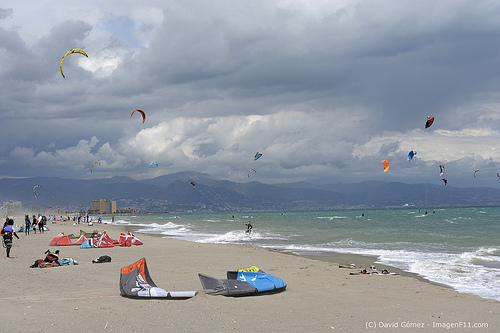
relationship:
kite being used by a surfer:
[379, 160, 390, 174] [244, 218, 253, 235]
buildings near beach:
[0, 195, 135, 215] [2, 219, 499, 331]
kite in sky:
[379, 160, 390, 174] [11, 17, 481, 197]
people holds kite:
[1, 218, 19, 261] [0, 227, 15, 257]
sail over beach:
[59, 45, 89, 78] [2, 200, 498, 330]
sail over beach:
[129, 109, 147, 125] [2, 200, 498, 330]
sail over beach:
[472, 167, 486, 182] [2, 200, 498, 330]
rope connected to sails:
[63, 78, 241, 227] [34, 34, 276, 219]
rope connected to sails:
[196, 194, 226, 213] [34, 34, 276, 219]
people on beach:
[1, 218, 19, 261] [2, 200, 498, 330]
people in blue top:
[1, 218, 19, 261] [0, 225, 15, 237]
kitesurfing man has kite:
[245, 220, 253, 234] [372, 155, 398, 177]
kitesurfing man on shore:
[245, 218, 254, 232] [5, 231, 493, 331]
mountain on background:
[4, 158, 499, 213] [5, 165, 498, 205]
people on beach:
[1, 205, 121, 268] [378, 276, 409, 291]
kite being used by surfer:
[411, 107, 448, 142] [240, 214, 259, 234]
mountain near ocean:
[0, 170, 500, 213] [100, 208, 499, 301]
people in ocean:
[1, 218, 19, 261] [60, 190, 498, 317]